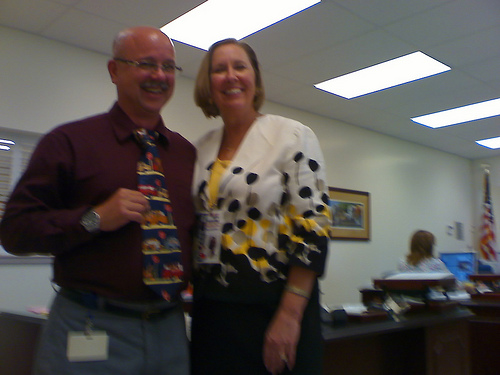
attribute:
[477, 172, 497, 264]
flag — american, red,white, blue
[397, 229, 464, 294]
lady — sitting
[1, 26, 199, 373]
man — bald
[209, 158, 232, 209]
shirt — yellow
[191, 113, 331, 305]
jacket — white,black, yellow, white,yellow, black, yellow,white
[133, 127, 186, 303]
tie — blue, colorful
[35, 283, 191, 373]
pants — gray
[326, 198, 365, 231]
picture — framed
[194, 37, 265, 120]
hair — short, light brown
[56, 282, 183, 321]
belt — black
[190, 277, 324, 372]
pants — black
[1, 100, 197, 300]
shirt — burgundy